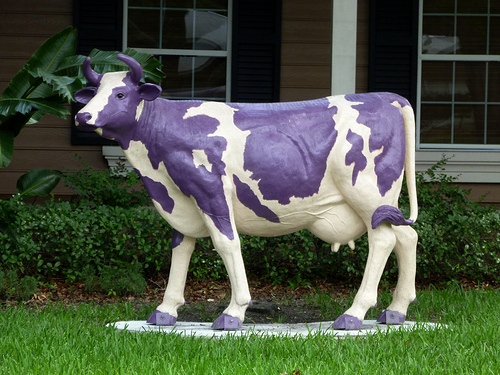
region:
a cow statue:
[72, 52, 428, 332]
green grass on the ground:
[47, 343, 164, 369]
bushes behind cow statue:
[0, 202, 498, 284]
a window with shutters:
[365, 0, 499, 181]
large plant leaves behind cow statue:
[0, 16, 162, 171]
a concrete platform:
[105, 305, 445, 335]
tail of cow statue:
[365, 83, 421, 233]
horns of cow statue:
[76, 53, 147, 86]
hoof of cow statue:
[202, 307, 242, 328]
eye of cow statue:
[114, 91, 125, 100]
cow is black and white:
[103, 61, 483, 320]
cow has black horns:
[89, 65, 148, 105]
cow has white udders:
[306, 209, 369, 275]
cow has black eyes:
[114, 88, 129, 110]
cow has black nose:
[77, 111, 91, 127]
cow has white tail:
[388, 96, 436, 221]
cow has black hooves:
[295, 284, 356, 339]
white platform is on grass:
[70, 300, 455, 363]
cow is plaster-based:
[74, 53, 431, 332]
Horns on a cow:
[78, 51, 145, 81]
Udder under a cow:
[312, 208, 373, 253]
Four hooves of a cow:
[137, 299, 429, 336]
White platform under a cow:
[106, 311, 455, 346]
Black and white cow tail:
[381, 89, 426, 234]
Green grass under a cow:
[116, 338, 456, 373]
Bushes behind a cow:
[67, 200, 444, 270]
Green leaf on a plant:
[13, 165, 66, 196]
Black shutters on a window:
[367, 3, 417, 106]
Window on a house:
[416, 4, 499, 143]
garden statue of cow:
[72, 52, 452, 336]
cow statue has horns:
[71, 60, 453, 345]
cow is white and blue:
[70, 47, 419, 332]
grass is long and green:
[1, 279, 498, 374]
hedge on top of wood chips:
[1, 196, 498, 303]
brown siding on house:
[1, 1, 498, 211]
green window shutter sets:
[72, 3, 419, 143]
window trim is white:
[96, 7, 498, 184]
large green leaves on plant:
[1, 25, 161, 175]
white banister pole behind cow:
[331, 2, 358, 95]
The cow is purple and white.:
[59, 53, 433, 332]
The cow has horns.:
[68, 42, 151, 92]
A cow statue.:
[70, 51, 435, 333]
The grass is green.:
[146, 347, 433, 374]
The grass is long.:
[118, 341, 380, 373]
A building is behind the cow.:
[0, 1, 496, 233]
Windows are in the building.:
[55, 0, 290, 184]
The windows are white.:
[120, 0, 235, 110]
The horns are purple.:
[72, 47, 151, 87]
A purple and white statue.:
[59, 47, 463, 347]